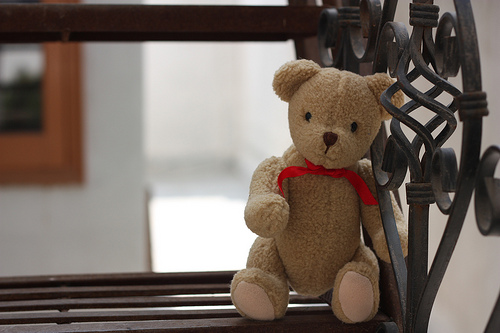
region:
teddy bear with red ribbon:
[225, 50, 391, 332]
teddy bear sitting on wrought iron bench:
[2, 2, 497, 323]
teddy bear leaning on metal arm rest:
[223, 55, 483, 321]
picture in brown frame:
[2, 44, 87, 190]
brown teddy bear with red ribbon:
[231, 60, 409, 326]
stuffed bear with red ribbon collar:
[243, 59, 410, 313]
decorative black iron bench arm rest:
[370, 4, 478, 330]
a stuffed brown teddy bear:
[268, 54, 405, 166]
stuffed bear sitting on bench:
[228, 53, 443, 331]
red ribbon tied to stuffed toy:
[277, 157, 377, 209]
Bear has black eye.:
[290, 105, 312, 117]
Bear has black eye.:
[338, 115, 393, 150]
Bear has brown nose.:
[311, 127, 336, 144]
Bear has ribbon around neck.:
[298, 143, 366, 201]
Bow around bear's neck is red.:
[277, 136, 367, 225]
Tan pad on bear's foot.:
[331, 265, 371, 330]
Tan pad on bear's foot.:
[232, 261, 279, 331]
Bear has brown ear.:
[282, 46, 305, 85]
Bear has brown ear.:
[369, 65, 414, 153]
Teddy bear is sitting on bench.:
[265, 65, 362, 330]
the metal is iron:
[387, 99, 479, 281]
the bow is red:
[275, 153, 372, 187]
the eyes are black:
[295, 107, 368, 131]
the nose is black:
[318, 123, 363, 153]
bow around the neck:
[280, 151, 381, 198]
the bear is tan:
[269, 69, 390, 320]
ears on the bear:
[276, 58, 391, 163]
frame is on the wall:
[3, 42, 122, 207]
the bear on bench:
[223, 72, 390, 328]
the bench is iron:
[66, 267, 316, 332]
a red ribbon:
[280, 152, 371, 200]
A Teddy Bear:
[235, 55, 400, 320]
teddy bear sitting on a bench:
[215, 40, 462, 330]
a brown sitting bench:
[0, 270, 225, 325]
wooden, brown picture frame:
[25, 41, 90, 183]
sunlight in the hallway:
[150, 50, 241, 265]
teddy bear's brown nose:
[317, 125, 337, 155]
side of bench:
[380, 6, 491, 327]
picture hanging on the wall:
[5, 42, 115, 212]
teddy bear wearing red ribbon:
[231, 55, 401, 323]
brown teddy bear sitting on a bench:
[227, 55, 411, 325]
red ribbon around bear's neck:
[275, 154, 377, 211]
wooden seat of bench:
[16, 268, 381, 325]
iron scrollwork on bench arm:
[365, 24, 492, 317]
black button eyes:
[302, 107, 362, 134]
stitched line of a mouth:
[309, 147, 343, 164]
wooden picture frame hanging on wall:
[6, 50, 101, 200]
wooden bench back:
[6, 2, 313, 49]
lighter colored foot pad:
[337, 266, 379, 319]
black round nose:
[318, 129, 341, 154]